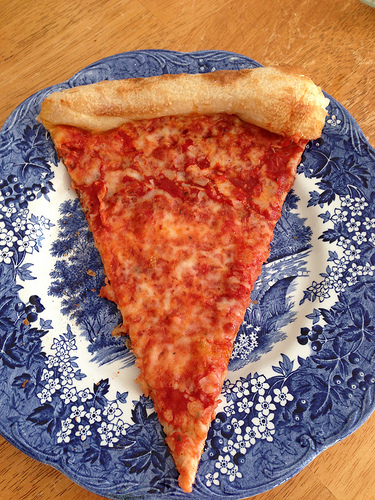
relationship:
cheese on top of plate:
[40, 65, 330, 493] [249, 218, 363, 435]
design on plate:
[0, 46, 373, 492] [54, 62, 371, 418]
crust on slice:
[42, 72, 321, 134] [38, 65, 331, 492]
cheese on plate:
[40, 65, 330, 493] [0, 39, 373, 483]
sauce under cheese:
[47, 113, 309, 493] [158, 219, 189, 236]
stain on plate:
[109, 369, 121, 380] [14, 73, 335, 443]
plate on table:
[0, 39, 373, 483] [1, 0, 373, 499]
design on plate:
[4, 46, 374, 487] [0, 39, 373, 483]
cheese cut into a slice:
[40, 65, 330, 493] [38, 65, 331, 492]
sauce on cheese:
[47, 113, 309, 493] [40, 65, 330, 493]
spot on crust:
[205, 70, 251, 87] [35, 65, 330, 141]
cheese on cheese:
[48, 114, 307, 493] [40, 65, 330, 493]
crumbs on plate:
[19, 271, 127, 395] [0, 39, 373, 483]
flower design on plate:
[6, 111, 374, 486] [0, 39, 373, 483]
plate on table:
[318, 162, 373, 260] [2, 0, 368, 54]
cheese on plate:
[40, 65, 330, 493] [318, 162, 373, 260]